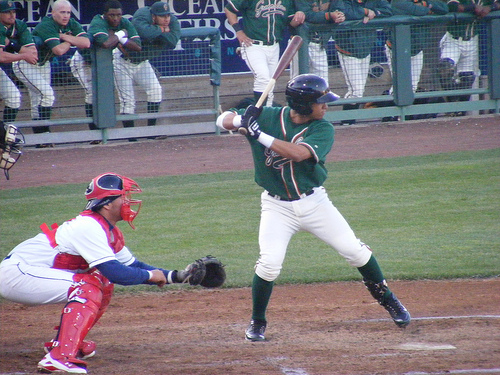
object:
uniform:
[216, 104, 396, 323]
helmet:
[84, 170, 143, 230]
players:
[109, 0, 183, 143]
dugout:
[0, 0, 500, 152]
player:
[211, 70, 414, 343]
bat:
[236, 33, 306, 136]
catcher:
[0, 169, 229, 375]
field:
[0, 67, 500, 375]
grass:
[0, 149, 500, 295]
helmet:
[283, 73, 341, 117]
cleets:
[243, 272, 274, 342]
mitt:
[170, 253, 229, 289]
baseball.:
[195, 29, 429, 343]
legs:
[242, 187, 297, 344]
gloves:
[240, 113, 262, 140]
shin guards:
[44, 265, 117, 358]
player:
[1, 169, 230, 375]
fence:
[0, 0, 499, 155]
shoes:
[242, 313, 272, 344]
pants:
[247, 179, 397, 326]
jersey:
[226, 106, 338, 202]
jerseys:
[221, 0, 299, 46]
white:
[0, 209, 138, 307]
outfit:
[0, 207, 182, 370]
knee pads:
[47, 270, 107, 367]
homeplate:
[0, 271, 500, 375]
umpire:
[0, 120, 27, 182]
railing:
[0, 10, 500, 48]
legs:
[0, 255, 108, 375]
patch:
[0, 148, 500, 292]